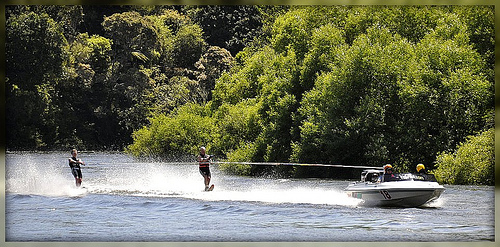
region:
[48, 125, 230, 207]
two people are waterskiing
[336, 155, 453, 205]
boat in the river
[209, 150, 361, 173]
ropes coming off of the boat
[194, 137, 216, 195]
person is on a water ski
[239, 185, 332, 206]
wake behind the boat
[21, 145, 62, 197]
water splashing behind the skier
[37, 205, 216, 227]
water in the river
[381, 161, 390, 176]
person driving the boat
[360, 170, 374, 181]
motor on the back of the boat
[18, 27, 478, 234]
Some people are out on the water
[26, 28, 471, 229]
Some people are in a speedboat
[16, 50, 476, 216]
Some people are doing some waterskiing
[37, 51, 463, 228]
Some people are pulled by a boat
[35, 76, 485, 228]
Some people are on their vacation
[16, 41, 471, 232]
Some people are close to some trees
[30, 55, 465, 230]
Some people are moving very fast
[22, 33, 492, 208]
Some people are out in the daytime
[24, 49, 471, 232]
Some people are enjoying their day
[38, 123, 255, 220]
two persons in the water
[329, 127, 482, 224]
a boat in water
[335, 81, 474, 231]
a ship in water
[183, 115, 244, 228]
a woman holding the ship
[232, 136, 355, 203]
a thread from boat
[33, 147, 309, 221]
raise of the water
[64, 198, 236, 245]
a cool view of water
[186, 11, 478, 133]
a green plants in the back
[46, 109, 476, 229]
people and boat in water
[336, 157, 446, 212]
boat in the water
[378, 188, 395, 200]
number 18 on the side of the boat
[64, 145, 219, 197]
two people waterskiing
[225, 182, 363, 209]
waves made by the boat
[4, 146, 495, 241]
body of water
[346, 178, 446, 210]
small white colored boat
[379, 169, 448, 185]
windshield on the boat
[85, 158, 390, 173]
rope pulling the skiiers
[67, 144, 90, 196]
skiier on the left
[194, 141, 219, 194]
skiier on the right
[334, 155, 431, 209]
a small white boat is driving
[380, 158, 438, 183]
two people are on a boat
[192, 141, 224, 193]
a person is riding some jet skis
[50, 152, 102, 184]
a guy is skiing on water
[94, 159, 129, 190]
the mist of some water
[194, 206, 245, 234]
the waves of the river water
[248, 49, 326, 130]
a bunch of leaves on a tree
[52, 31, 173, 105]
a group of green trees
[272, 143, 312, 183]
the line for jet skiing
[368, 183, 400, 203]
the number of a boat